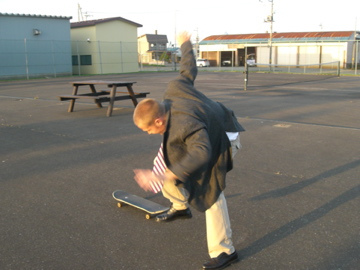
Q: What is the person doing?
A: Raising a foot.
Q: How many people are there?
A: One.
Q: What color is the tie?
A: Red and white.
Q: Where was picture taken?
A: In parking lot.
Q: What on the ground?
A: Skateboard.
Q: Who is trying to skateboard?
A: A man.